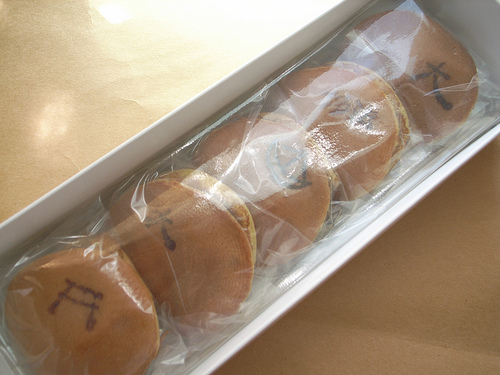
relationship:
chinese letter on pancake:
[47, 275, 109, 329] [3, 3, 488, 374]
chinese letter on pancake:
[141, 208, 178, 250] [3, 3, 488, 374]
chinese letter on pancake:
[264, 140, 312, 190] [3, 3, 488, 374]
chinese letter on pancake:
[413, 57, 452, 109] [3, 3, 488, 374]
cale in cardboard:
[347, 7, 477, 143] [2, 2, 498, 374]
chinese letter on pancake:
[142, 206, 177, 253] [107, 177, 258, 318]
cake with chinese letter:
[0, 238, 178, 368] [47, 277, 105, 332]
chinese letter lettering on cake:
[415, 61, 452, 111] [0, 238, 178, 368]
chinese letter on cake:
[47, 277, 105, 332] [0, 238, 178, 368]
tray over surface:
[2, 0, 496, 373] [361, 252, 498, 374]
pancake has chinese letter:
[265, 58, 412, 199] [327, 82, 379, 136]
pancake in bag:
[3, 3, 488, 374] [3, 187, 196, 373]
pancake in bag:
[335, 8, 478, 144] [0, 0, 498, 373]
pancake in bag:
[265, 58, 412, 199] [0, 0, 498, 373]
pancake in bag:
[191, 111, 333, 267] [0, 0, 498, 373]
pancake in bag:
[107, 167, 257, 324] [0, 0, 498, 373]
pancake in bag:
[2, 234, 159, 373] [0, 0, 498, 373]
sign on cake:
[416, 60, 456, 110] [354, 5, 481, 147]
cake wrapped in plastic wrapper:
[0, 238, 178, 368] [0, 220, 191, 374]